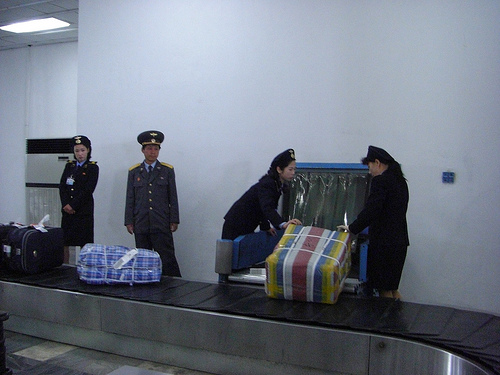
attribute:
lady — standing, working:
[335, 141, 412, 307]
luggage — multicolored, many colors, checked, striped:
[260, 216, 356, 309]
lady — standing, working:
[211, 144, 305, 274]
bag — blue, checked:
[74, 241, 171, 292]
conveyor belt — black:
[3, 257, 493, 374]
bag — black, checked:
[3, 215, 67, 280]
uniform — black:
[348, 171, 411, 294]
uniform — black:
[212, 174, 288, 239]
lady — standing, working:
[54, 134, 102, 260]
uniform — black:
[58, 158, 100, 246]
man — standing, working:
[121, 127, 188, 281]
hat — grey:
[135, 126, 169, 152]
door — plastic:
[287, 168, 373, 240]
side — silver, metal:
[2, 281, 483, 374]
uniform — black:
[123, 162, 188, 282]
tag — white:
[111, 246, 140, 270]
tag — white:
[32, 222, 51, 237]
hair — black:
[360, 156, 408, 182]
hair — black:
[266, 161, 292, 181]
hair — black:
[84, 144, 92, 163]